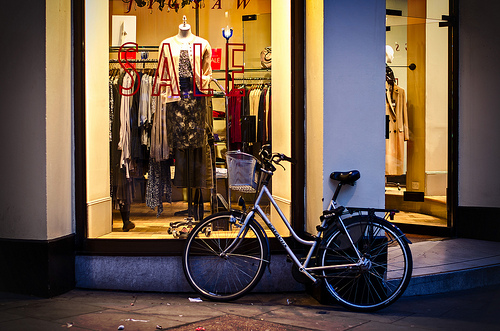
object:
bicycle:
[180, 144, 418, 314]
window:
[106, 0, 296, 235]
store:
[0, 0, 455, 240]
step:
[413, 245, 500, 300]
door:
[385, 9, 457, 232]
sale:
[114, 37, 248, 104]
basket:
[219, 150, 262, 189]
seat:
[329, 164, 361, 190]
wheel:
[179, 210, 270, 305]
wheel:
[314, 214, 414, 313]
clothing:
[231, 87, 273, 148]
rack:
[222, 70, 270, 85]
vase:
[104, 12, 142, 50]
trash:
[180, 291, 204, 307]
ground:
[119, 301, 184, 331]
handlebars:
[253, 143, 295, 169]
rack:
[321, 200, 348, 222]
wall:
[300, 0, 386, 169]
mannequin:
[154, 16, 216, 225]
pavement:
[0, 305, 500, 330]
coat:
[383, 80, 415, 178]